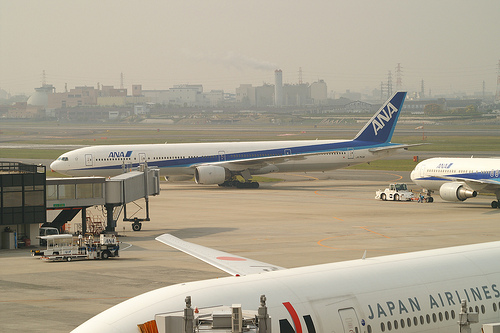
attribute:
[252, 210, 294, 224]
clear ground — clean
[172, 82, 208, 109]
brick building — beige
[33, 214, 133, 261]
business truck — white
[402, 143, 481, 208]
plane — white, blue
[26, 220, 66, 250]
truck — parked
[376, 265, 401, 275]
plane — white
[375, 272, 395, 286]
plane — white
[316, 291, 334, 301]
plane — white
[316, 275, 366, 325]
plane — white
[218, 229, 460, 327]
plane — white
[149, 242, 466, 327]
plane — white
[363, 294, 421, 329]
letters — green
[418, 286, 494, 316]
letters — green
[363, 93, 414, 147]
tail — blue, white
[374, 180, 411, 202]
truck — white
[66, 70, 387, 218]
plane — blue, white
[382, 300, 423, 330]
windows — small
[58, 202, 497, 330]
airplane — red, white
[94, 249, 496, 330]
plane — white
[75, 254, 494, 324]
plane — white